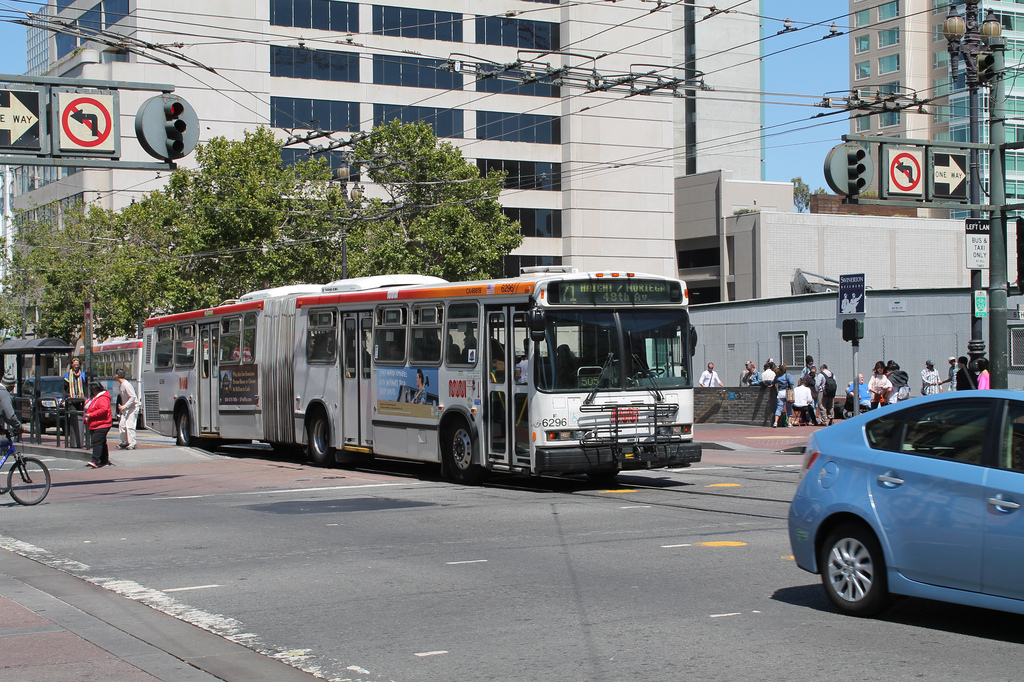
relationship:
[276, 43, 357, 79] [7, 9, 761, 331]
window on a building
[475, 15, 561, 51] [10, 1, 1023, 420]
window on a building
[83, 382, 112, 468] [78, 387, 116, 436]
handle wearing a coat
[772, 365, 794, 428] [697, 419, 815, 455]
people on sidewalk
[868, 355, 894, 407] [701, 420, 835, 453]
person on sidewalk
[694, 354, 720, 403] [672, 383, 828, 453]
person on sidewalk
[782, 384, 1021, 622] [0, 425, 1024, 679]
car on street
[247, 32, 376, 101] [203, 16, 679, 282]
windows on building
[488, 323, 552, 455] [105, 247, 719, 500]
door on bus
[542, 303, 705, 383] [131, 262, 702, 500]
windshield on bus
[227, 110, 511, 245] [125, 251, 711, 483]
trees next to bus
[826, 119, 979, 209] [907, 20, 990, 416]
street signs on post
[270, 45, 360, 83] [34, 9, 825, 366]
window on building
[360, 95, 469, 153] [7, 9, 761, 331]
window on building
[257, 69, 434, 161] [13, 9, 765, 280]
window on building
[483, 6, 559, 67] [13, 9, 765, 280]
window on building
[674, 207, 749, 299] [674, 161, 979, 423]
window on building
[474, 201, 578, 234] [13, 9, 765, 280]
window on building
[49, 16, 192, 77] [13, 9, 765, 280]
window on building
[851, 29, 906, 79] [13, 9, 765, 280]
window on building